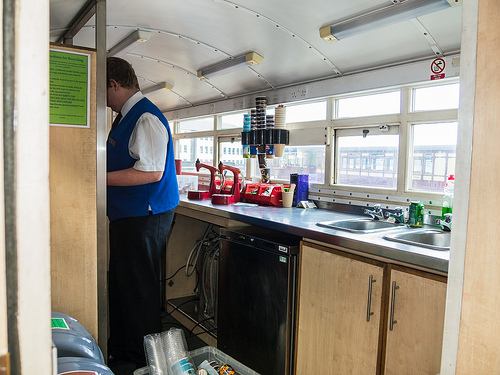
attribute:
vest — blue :
[112, 99, 178, 210]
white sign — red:
[429, 48, 446, 83]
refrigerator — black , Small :
[213, 228, 290, 373]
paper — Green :
[47, 49, 90, 128]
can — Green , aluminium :
[407, 202, 424, 226]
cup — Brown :
[283, 189, 293, 206]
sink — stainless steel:
[310, 215, 408, 234]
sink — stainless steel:
[388, 225, 456, 257]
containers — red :
[210, 161, 300, 208]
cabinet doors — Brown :
[296, 235, 450, 373]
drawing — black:
[432, 59, 443, 70]